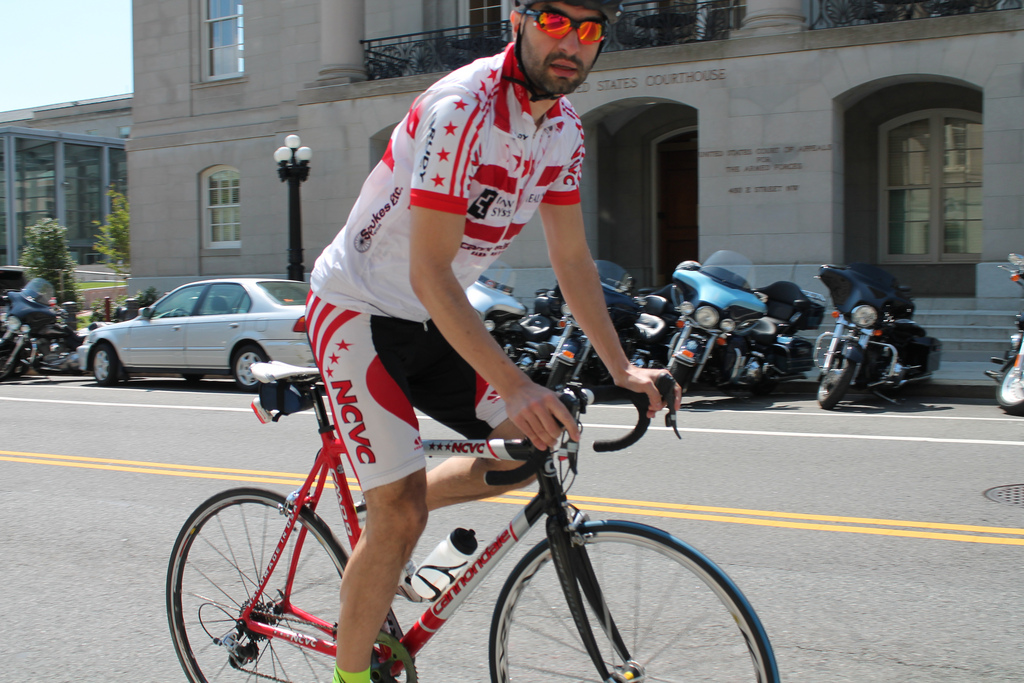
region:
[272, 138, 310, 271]
a street lamp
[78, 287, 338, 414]
a silver car parked on the street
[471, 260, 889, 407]
motorcycles parked on the street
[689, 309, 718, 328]
a headlight on the motorcycle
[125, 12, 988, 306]
a large white building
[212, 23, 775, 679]
a man on a bicycle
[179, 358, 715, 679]
a red and white bicycle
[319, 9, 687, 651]
a man wearing glasses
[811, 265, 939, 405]
A large black motorcycle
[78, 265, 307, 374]
A silver car my a lamp pole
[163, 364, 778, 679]
A red and white bicycle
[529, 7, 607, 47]
A pair of orange eye shades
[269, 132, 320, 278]
A black lamp pole with three gloves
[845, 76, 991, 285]
A large window in front of building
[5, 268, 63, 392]
A motorcycle is front of a car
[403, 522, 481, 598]
A white water bottle with a black cap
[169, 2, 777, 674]
man with orange sunglasses riding a bike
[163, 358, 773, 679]
a red and black bike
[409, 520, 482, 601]
a white water bottle with black cap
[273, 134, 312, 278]
white streetlamps on a metal pole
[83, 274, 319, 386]
a parked silver car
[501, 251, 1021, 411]
a row of parked motorcycles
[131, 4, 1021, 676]
a man riding a bike in front of a courthouse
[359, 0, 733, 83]
a black metal fence on a balcony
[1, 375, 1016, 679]
yellow lines on a street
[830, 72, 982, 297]
a closed white window behind an arch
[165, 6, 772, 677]
Man riding red and white bicycle.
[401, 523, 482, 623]
Water bottle attached to bicycle frame.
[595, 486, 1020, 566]
Double yellow line on street.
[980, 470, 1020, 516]
A metal manhole cover.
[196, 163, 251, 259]
White framed window on building.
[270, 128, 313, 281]
Street lamps on top of metal pole.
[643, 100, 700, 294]
Large, dark colored door.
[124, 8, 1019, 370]
A United States courthouse building.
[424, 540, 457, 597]
the bottle is white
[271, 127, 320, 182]
the light covers are white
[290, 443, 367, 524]
the bike is red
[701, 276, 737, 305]
the motorcycle is blue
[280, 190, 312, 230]
the pole is black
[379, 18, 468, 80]
the barrier on the balcony is black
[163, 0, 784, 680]
a man riding a bike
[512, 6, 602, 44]
Glasses are neon orange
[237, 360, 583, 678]
THe bike frame is red and white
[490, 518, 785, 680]
front wheel of the bike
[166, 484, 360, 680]
back wheel of the bike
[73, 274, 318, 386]
A silver car is parked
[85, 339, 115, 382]
front tire is black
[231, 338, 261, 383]
back tire is black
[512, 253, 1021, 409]
line of motorcycles are parked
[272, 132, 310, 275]
Black pole with three lights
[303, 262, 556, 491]
white and black shorts with red designs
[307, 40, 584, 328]
red and white designed shirt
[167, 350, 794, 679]
red and white bicycle with black handlebars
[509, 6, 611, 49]
red mirrored glasses with black frames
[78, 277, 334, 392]
white car parked beside a building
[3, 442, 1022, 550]
yellow lines running down middle of gray street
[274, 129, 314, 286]
street light standing on a black post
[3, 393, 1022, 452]
white lines painted on the side of a street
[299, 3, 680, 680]
The cyclist is riding the bbike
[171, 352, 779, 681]
The bike udner the cyclist